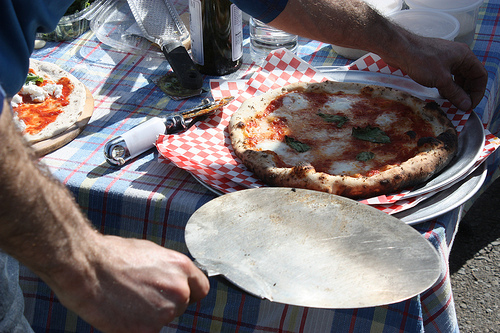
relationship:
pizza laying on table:
[28, 57, 95, 167] [9, 0, 496, 245]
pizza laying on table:
[228, 80, 457, 194] [9, 0, 498, 330]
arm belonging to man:
[0, 112, 99, 273] [0, 0, 491, 333]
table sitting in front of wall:
[58, 70, 192, 211] [437, 230, 489, 300]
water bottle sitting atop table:
[247, 16, 298, 66] [24, 19, 499, 314]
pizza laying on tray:
[228, 80, 457, 194] [232, 65, 484, 215]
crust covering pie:
[228, 79, 456, 194] [223, 78, 454, 195]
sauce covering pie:
[253, 97, 433, 171] [223, 78, 454, 195]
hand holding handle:
[52, 232, 214, 331] [119, 234, 246, 325]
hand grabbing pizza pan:
[403, 34, 490, 112] [179, 62, 485, 202]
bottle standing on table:
[163, 10, 275, 96] [33, 33, 466, 270]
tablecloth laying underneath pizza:
[6, 2, 495, 331] [228, 80, 457, 194]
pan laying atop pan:
[294, 70, 486, 203] [381, 157, 486, 222]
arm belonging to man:
[0, 112, 90, 262] [0, 0, 491, 333]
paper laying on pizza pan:
[152, 47, 500, 212] [179, 69, 486, 199]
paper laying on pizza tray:
[211, 49, 484, 221] [185, 61, 480, 228]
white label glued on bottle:
[231, 4, 243, 60] [192, 1, 243, 76]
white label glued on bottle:
[190, 0, 202, 62] [192, 1, 243, 76]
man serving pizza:
[4, 100, 198, 332] [246, 93, 459, 245]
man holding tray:
[0, 0, 491, 333] [182, 184, 445, 309]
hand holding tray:
[52, 230, 212, 331] [182, 184, 445, 309]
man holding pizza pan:
[0, 0, 491, 333] [179, 69, 486, 199]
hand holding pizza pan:
[409, 34, 490, 115] [179, 69, 486, 199]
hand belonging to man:
[52, 230, 212, 331] [0, 0, 491, 333]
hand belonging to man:
[409, 34, 490, 115] [0, 0, 491, 333]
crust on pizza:
[224, 79, 459, 198] [228, 80, 458, 198]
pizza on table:
[228, 80, 458, 198] [9, 0, 498, 330]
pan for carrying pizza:
[180, 182, 447, 313] [228, 80, 458, 198]